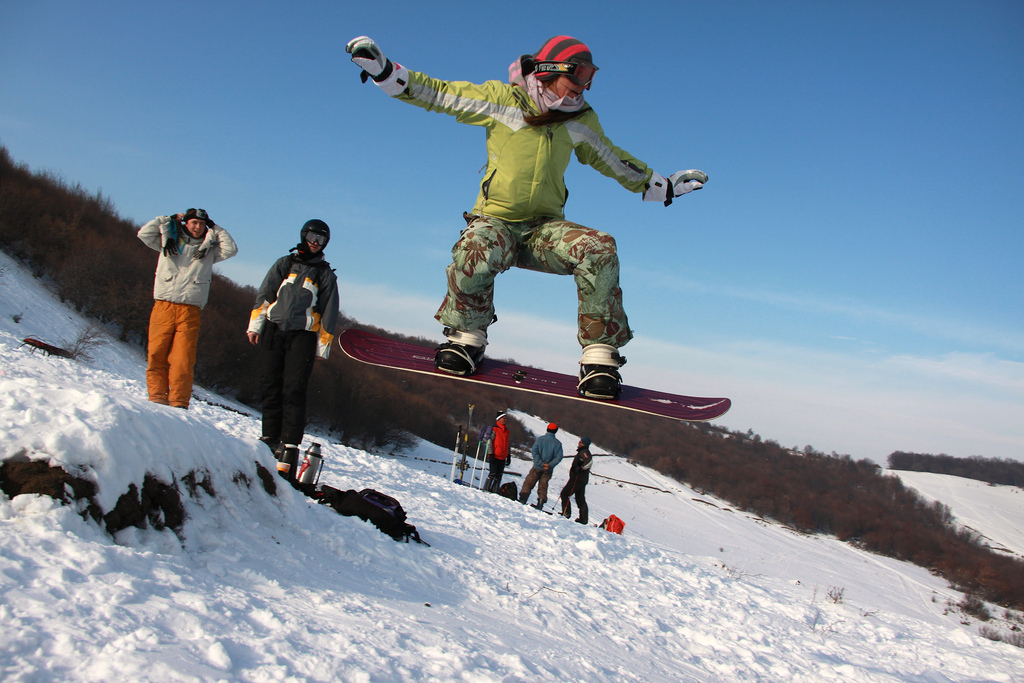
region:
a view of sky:
[129, 3, 323, 156]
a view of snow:
[408, 518, 598, 645]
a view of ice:
[97, 446, 252, 536]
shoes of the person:
[398, 316, 673, 444]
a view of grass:
[723, 389, 897, 514]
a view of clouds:
[698, 209, 895, 386]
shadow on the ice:
[272, 505, 472, 639]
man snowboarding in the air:
[329, 29, 734, 429]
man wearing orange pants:
[133, 205, 241, 408]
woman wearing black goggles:
[241, 216, 340, 479]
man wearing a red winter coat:
[484, 401, 517, 503]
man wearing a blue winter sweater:
[514, 416, 563, 512]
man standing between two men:
[517, 420, 562, 515]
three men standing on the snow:
[473, 404, 597, 531]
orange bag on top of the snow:
[589, 509, 628, 538]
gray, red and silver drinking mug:
[292, 433, 325, 500]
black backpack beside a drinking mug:
[315, 471, 426, 545]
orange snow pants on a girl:
[139, 301, 207, 407]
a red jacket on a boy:
[489, 417, 513, 465]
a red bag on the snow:
[600, 512, 630, 531]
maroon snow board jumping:
[344, 322, 725, 424]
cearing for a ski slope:
[853, 439, 1021, 556]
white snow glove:
[654, 148, 712, 212]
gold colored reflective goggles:
[534, 53, 596, 92]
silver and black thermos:
[297, 437, 323, 495]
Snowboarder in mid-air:
[335, 17, 732, 422]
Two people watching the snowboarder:
[133, 205, 343, 461]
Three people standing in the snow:
[477, 404, 599, 526]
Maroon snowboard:
[332, 319, 735, 419]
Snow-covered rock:
[0, 372, 413, 570]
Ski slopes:
[0, 262, 1019, 677]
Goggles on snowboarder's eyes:
[520, 50, 597, 83]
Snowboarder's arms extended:
[338, 22, 711, 194]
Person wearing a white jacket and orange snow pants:
[133, 202, 241, 409]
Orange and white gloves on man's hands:
[242, 305, 341, 363]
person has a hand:
[343, 37, 392, 80]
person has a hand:
[671, 166, 710, 199]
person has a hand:
[317, 346, 330, 366]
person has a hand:
[167, 213, 184, 230]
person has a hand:
[207, 219, 215, 239]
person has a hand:
[542, 458, 549, 471]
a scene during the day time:
[54, 28, 838, 646]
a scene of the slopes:
[32, 246, 997, 680]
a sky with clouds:
[5, 4, 1023, 483]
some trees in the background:
[2, 129, 1021, 632]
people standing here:
[106, 181, 765, 622]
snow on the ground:
[5, 256, 941, 680]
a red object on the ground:
[590, 506, 629, 535]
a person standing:
[130, 177, 248, 431]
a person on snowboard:
[262, 16, 753, 494]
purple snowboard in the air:
[334, 323, 733, 423]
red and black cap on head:
[526, 32, 594, 72]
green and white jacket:
[371, 66, 666, 221]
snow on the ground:
[4, 252, 1020, 679]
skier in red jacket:
[484, 410, 510, 491]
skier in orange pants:
[137, 208, 235, 408]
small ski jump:
[2, 337, 296, 560]